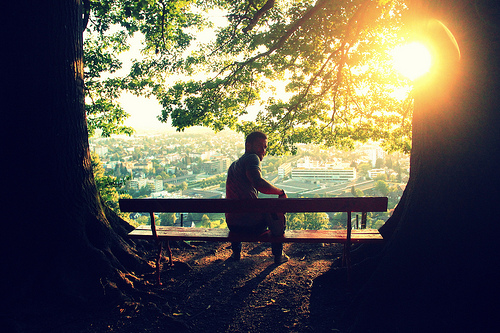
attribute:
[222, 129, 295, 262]
person — sitting, turning away, looking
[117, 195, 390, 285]
bench — brown, red, wood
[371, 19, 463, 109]
sun — orange, setting, shining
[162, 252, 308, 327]
dirt — brown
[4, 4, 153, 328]
tree — large, brown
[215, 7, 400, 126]
branch — green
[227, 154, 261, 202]
tshirt — grey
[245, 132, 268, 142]
hair — short